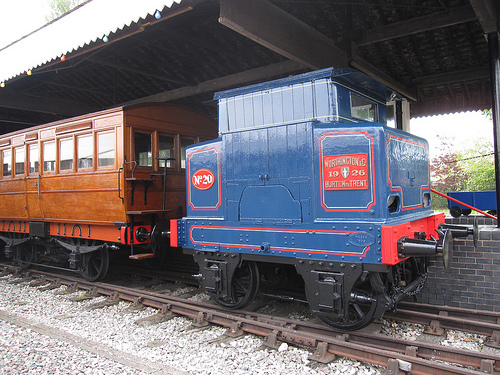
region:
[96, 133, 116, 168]
glass window on train car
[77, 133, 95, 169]
glass window on train car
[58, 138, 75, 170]
glass window on train car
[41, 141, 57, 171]
glass window on train car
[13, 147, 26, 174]
glass window on train car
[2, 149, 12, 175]
glass window on train car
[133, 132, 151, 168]
glass window on train car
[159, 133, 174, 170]
glass window on train car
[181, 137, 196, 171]
glass window on train car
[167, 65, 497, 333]
a blue and red train car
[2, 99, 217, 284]
a brown train car in front of a blue train car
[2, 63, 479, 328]
brown and blue train cars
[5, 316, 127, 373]
gray rocks on the ground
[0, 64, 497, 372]
two train cars on the tracks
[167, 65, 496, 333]
a blue and red train car behind another train car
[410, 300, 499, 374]
heavy metal railroad tracks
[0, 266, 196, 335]
gravels beside the tracks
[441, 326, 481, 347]
gravel between the tracks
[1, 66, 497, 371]
two train cars on railroad tracks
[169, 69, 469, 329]
small blue caboose on the train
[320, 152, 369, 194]
red and gold sign on the train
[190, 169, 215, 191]
red and white sign that says "No 20"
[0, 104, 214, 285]
passenger car on the train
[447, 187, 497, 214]
blue wagon on the platform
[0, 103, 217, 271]
train car with wood paneling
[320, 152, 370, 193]
sign with the number 1926 on it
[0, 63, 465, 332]
train stopped at the station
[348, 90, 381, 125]
window on the blue casboose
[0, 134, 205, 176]
windows on the passenger car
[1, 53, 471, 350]
train on the tracks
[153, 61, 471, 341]
blue and red train car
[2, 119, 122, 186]
a row of windows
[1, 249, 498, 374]
gravel around the train tracks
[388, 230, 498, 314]
wall is made of bricks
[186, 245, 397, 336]
two black wheels under the train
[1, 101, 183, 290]
burnt orange train car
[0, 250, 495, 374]
a set of train tracks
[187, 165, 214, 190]
red and white logo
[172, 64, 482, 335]
large metal blue train car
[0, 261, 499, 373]
large long rusty train track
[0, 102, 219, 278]
long brown metal train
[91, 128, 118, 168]
large square glass window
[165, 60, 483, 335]
a blue train car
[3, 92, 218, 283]
An orange train car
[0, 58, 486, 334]
Two railroad cars connected together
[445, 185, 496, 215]
A blue object with wheels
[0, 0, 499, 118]
A tin roof supported by steel beams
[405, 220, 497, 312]
grey brick wall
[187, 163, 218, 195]
a red sign that says number 20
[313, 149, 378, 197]
A red sign with white text